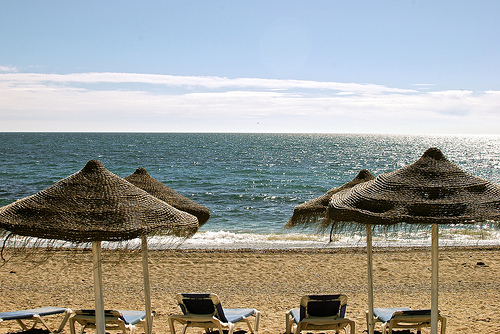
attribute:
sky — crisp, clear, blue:
[2, 2, 499, 89]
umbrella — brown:
[2, 160, 200, 245]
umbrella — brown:
[120, 166, 210, 225]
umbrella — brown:
[329, 146, 499, 239]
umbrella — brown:
[283, 168, 372, 229]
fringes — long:
[2, 228, 191, 258]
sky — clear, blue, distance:
[259, 13, 457, 67]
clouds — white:
[116, 91, 329, 133]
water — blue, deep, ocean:
[179, 137, 301, 187]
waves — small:
[200, 221, 289, 249]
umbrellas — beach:
[291, 151, 471, 239]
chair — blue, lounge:
[362, 301, 435, 332]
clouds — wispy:
[4, 73, 487, 131]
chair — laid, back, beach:
[75, 298, 145, 332]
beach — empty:
[71, 287, 154, 316]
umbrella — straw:
[318, 149, 495, 238]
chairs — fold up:
[281, 291, 447, 331]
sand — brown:
[4, 244, 496, 326]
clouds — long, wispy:
[1, 59, 499, 136]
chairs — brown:
[6, 288, 445, 332]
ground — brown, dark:
[0, 245, 496, 332]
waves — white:
[2, 228, 499, 247]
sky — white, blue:
[2, 2, 498, 132]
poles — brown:
[363, 223, 439, 330]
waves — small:
[211, 226, 311, 246]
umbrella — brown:
[322, 144, 496, 222]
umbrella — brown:
[283, 191, 353, 228]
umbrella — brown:
[127, 163, 208, 214]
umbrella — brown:
[4, 166, 200, 239]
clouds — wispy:
[233, 77, 498, 129]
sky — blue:
[2, 4, 498, 77]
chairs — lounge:
[157, 280, 455, 332]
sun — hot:
[6, 7, 491, 332]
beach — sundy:
[190, 244, 319, 285]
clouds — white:
[2, 67, 498, 130]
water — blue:
[184, 136, 316, 190]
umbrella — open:
[6, 149, 209, 263]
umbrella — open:
[317, 140, 498, 230]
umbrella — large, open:
[286, 164, 400, 233]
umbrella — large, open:
[117, 158, 220, 243]